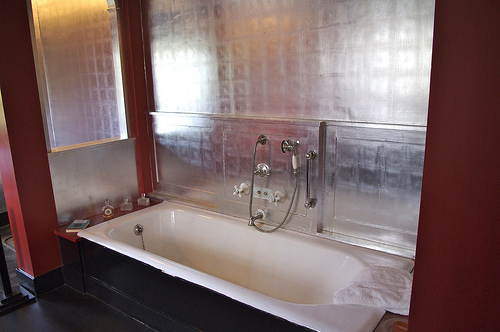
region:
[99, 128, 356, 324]
a bath tub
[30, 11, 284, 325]
a bath tub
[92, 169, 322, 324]
the bath tub is empty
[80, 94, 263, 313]
the bath tub is empty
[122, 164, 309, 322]
A bath tub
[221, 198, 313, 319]
A bath tub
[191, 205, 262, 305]
A bath tub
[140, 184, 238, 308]
A bath tub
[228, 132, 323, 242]
A shower head.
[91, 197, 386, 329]
A bathtub.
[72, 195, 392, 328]
The bathtub is white.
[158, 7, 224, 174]
The wall is made of glass.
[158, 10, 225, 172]
The glass is frosted.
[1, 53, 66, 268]
The walls are red.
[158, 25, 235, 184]
Light is refelcting on the wall.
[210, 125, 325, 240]
Knobs are on the tub.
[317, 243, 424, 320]
A towel is on the tub.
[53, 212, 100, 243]
A book.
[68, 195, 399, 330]
black and white porcelain bathrub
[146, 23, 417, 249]
silver colored walls behind bathtub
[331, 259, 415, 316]
fluffy white towel on side of bathtub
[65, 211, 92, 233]
book sitting beside bathtub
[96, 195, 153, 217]
perfume bottles sitting beside bathtub.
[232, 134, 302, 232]
silver and white faucet and showerhead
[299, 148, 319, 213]
handrail for getting up in the bathtub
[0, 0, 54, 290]
red and black support beam for wall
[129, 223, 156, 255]
draining device for bathtub.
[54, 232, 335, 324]
black wall outside bathtub